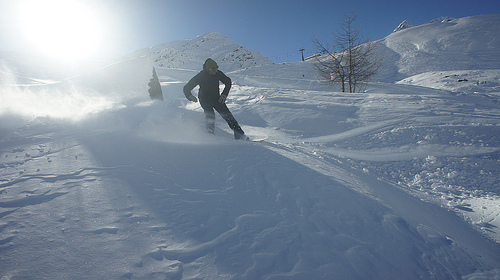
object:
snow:
[90, 123, 469, 248]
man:
[180, 57, 252, 142]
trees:
[303, 7, 388, 94]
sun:
[2, 0, 118, 68]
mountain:
[115, 30, 276, 70]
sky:
[183, 1, 290, 36]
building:
[304, 51, 326, 61]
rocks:
[459, 80, 476, 90]